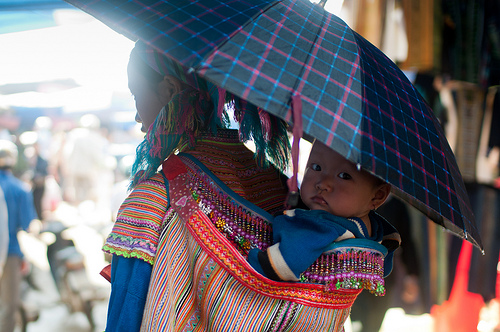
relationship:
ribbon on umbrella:
[289, 93, 301, 188] [69, 0, 484, 247]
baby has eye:
[253, 133, 392, 272] [336, 169, 353, 181]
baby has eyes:
[253, 133, 392, 272] [296, 151, 364, 195]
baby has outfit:
[253, 133, 392, 272] [244, 205, 370, 280]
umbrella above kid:
[69, 0, 484, 247] [245, 135, 402, 297]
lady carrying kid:
[95, 34, 298, 332] [285, 134, 371, 256]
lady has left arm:
[95, 34, 298, 329] [103, 169, 180, 329]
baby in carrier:
[253, 133, 392, 272] [129, 161, 381, 331]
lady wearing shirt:
[95, 34, 298, 332] [124, 142, 266, 220]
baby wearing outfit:
[253, 133, 392, 272] [251, 201, 373, 286]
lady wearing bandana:
[95, 34, 298, 332] [127, 40, 213, 187]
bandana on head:
[127, 40, 213, 187] [115, 40, 230, 155]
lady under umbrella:
[95, 34, 298, 332] [178, 3, 476, 144]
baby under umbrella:
[253, 133, 392, 272] [178, 3, 476, 144]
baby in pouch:
[253, 133, 392, 272] [141, 195, 391, 330]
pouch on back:
[141, 195, 391, 330] [154, 140, 286, 267]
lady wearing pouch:
[95, 34, 298, 332] [141, 195, 391, 330]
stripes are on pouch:
[125, 188, 165, 212] [139, 161, 371, 329]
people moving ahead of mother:
[6, 91, 117, 320] [105, 33, 331, 326]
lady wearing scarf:
[95, 34, 298, 332] [130, 39, 288, 189]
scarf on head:
[130, 39, 288, 189] [127, 38, 223, 138]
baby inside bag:
[267, 127, 396, 267] [147, 229, 387, 329]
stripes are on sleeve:
[125, 188, 165, 212] [100, 170, 168, 259]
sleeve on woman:
[100, 170, 168, 259] [101, 36, 258, 297]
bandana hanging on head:
[127, 40, 213, 187] [126, 37, 226, 147]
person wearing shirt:
[0, 136, 37, 331] [2, 171, 38, 257]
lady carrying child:
[95, 34, 298, 332] [236, 138, 387, 285]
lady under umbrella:
[95, 34, 298, 332] [130, 0, 474, 255]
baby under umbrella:
[253, 133, 392, 272] [130, 0, 474, 255]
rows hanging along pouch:
[199, 178, 206, 205] [134, 149, 394, 330]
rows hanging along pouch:
[196, 177, 389, 298] [134, 149, 394, 330]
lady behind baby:
[95, 34, 298, 332] [288, 128, 397, 228]